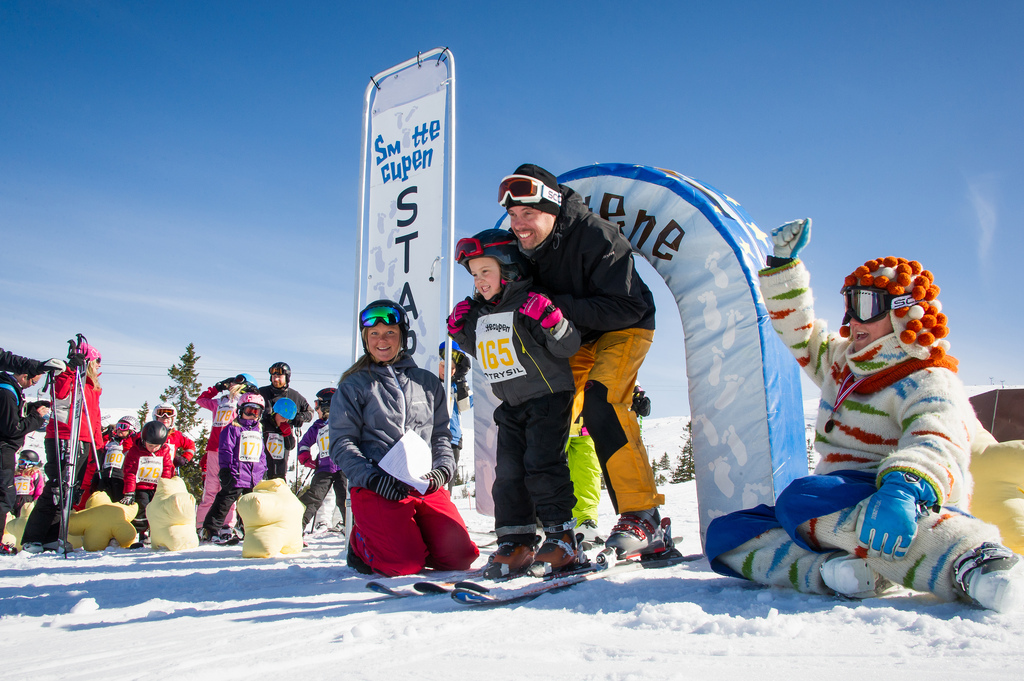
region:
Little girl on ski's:
[400, 230, 610, 598]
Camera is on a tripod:
[59, 335, 110, 551]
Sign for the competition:
[359, 50, 449, 345]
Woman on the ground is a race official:
[333, 301, 479, 570]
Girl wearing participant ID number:
[469, 312, 523, 386]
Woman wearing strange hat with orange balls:
[846, 258, 952, 366]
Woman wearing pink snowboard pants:
[345, 483, 481, 575]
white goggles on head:
[493, 170, 557, 216]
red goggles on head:
[441, 232, 498, 270]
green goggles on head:
[350, 298, 407, 328]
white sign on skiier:
[476, 318, 525, 388]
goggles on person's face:
[827, 284, 895, 341]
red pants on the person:
[340, 488, 489, 580]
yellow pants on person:
[566, 328, 672, 532]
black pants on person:
[477, 385, 592, 537]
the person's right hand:
[751, 205, 827, 283]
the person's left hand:
[852, 472, 941, 568]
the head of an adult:
[471, 165, 576, 261]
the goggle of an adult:
[494, 162, 558, 214]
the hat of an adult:
[506, 154, 582, 221]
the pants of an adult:
[529, 329, 675, 554]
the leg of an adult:
[555, 329, 677, 527]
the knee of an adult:
[579, 385, 625, 434]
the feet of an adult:
[535, 531, 684, 571]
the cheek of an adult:
[529, 215, 561, 241]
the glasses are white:
[497, 175, 575, 223]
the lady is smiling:
[352, 302, 411, 369]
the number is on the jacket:
[473, 305, 530, 400]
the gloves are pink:
[441, 289, 552, 331]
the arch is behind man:
[497, 184, 808, 584]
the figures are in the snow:
[87, 465, 315, 567]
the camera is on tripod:
[62, 334, 127, 537]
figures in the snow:
[80, 490, 328, 567]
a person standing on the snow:
[229, 385, 267, 512]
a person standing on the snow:
[302, 358, 380, 535]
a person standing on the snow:
[249, 353, 307, 446]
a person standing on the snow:
[121, 399, 211, 565]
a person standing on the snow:
[91, 398, 142, 535]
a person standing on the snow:
[36, 334, 148, 522]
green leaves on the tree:
[165, 366, 200, 409]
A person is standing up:
[246, 361, 322, 514]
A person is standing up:
[176, 362, 257, 556]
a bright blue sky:
[40, 54, 1011, 601]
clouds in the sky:
[15, 186, 407, 428]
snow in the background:
[33, 78, 958, 677]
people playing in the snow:
[40, 133, 859, 620]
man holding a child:
[444, 107, 776, 583]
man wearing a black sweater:
[407, 82, 736, 583]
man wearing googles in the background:
[375, 43, 736, 575]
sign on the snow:
[280, 29, 595, 630]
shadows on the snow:
[71, 505, 836, 638]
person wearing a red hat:
[770, 148, 1011, 408]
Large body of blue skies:
[878, 69, 1006, 212]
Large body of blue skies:
[91, 81, 260, 209]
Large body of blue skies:
[12, 25, 203, 264]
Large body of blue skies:
[69, 35, 244, 182]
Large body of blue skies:
[25, 15, 267, 249]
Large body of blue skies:
[187, 42, 308, 151]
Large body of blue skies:
[738, 29, 901, 176]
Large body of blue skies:
[79, 50, 285, 205]